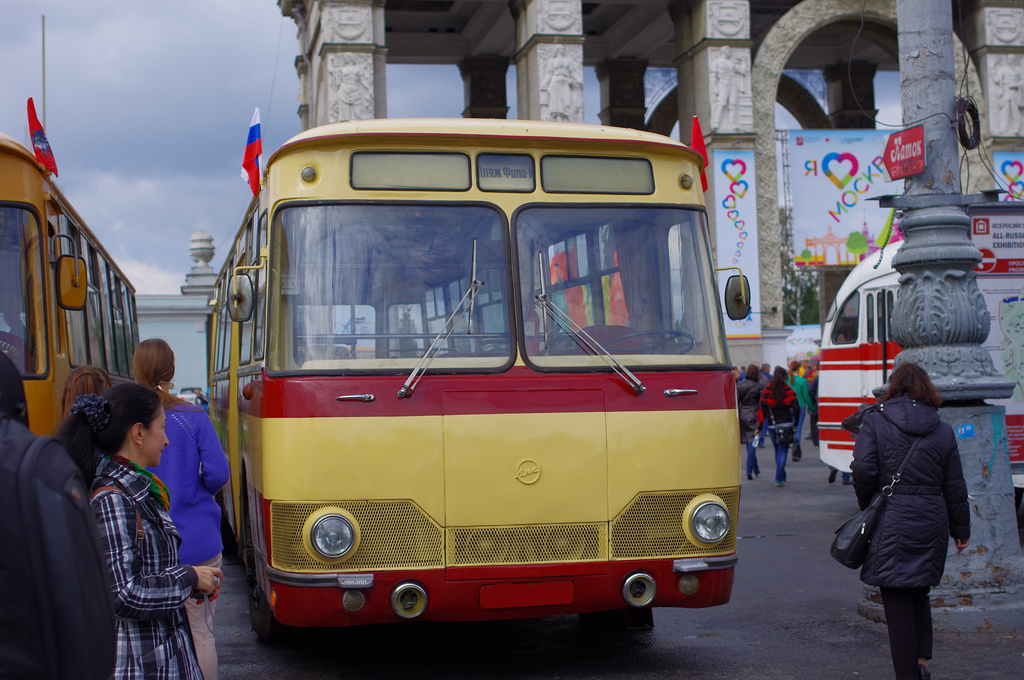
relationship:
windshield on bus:
[533, 211, 712, 352] [195, 111, 747, 658]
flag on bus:
[241, 110, 271, 215] [195, 111, 747, 658]